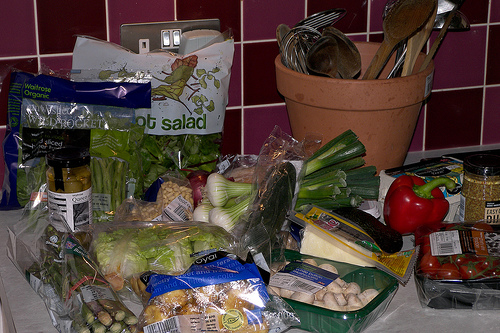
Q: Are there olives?
A: Yes, there are olives.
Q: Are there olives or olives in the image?
A: Yes, there are olives.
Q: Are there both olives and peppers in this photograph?
A: Yes, there are both olives and a pepper.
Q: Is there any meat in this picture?
A: No, there is no meat.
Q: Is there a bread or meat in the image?
A: No, there are no meat or breads.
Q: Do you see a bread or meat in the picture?
A: No, there are no meat or breads.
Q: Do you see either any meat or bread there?
A: No, there are no meat or breads.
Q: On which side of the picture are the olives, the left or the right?
A: The olives are on the left of the image.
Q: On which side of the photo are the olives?
A: The olives are on the left of the image.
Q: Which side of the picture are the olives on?
A: The olives are on the left of the image.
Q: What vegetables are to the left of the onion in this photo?
A: The vegetables are olives.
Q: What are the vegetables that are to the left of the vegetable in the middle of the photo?
A: The vegetables are olives.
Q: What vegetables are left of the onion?
A: The vegetables are olives.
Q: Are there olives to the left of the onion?
A: Yes, there are olives to the left of the onion.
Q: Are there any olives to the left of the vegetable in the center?
A: Yes, there are olives to the left of the onion.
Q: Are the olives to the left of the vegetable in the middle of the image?
A: Yes, the olives are to the left of the onion.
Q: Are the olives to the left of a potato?
A: No, the olives are to the left of the onion.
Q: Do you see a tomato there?
A: Yes, there is a tomato.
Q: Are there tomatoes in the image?
A: Yes, there is a tomato.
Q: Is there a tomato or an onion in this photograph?
A: Yes, there is a tomato.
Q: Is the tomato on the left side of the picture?
A: No, the tomato is on the right of the image.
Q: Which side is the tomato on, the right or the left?
A: The tomato is on the right of the image.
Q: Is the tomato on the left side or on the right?
A: The tomato is on the right of the image.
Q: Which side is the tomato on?
A: The tomato is on the right of the image.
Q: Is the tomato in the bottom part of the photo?
A: Yes, the tomato is in the bottom of the image.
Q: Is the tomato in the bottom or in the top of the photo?
A: The tomato is in the bottom of the image.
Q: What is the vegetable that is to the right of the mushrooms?
A: The vegetable is a tomato.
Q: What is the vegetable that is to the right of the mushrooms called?
A: The vegetable is a tomato.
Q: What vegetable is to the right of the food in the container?
A: The vegetable is a tomato.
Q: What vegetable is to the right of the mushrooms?
A: The vegetable is a tomato.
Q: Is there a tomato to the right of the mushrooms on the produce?
A: Yes, there is a tomato to the right of the mushrooms.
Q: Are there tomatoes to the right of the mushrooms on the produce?
A: Yes, there is a tomato to the right of the mushrooms.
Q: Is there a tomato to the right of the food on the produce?
A: Yes, there is a tomato to the right of the mushrooms.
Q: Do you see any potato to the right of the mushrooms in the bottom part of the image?
A: No, there is a tomato to the right of the mushrooms.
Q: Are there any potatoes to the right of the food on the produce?
A: No, there is a tomato to the right of the mushrooms.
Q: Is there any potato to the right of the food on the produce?
A: No, there is a tomato to the right of the mushrooms.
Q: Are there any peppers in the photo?
A: Yes, there is a pepper.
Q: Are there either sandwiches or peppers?
A: Yes, there is a pepper.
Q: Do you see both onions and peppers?
A: Yes, there are both a pepper and an onion.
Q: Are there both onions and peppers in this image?
A: Yes, there are both a pepper and an onion.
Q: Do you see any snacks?
A: No, there are no snacks.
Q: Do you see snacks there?
A: No, there are no snacks.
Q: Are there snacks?
A: No, there are no snacks.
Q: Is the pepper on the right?
A: Yes, the pepper is on the right of the image.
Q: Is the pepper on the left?
A: No, the pepper is on the right of the image.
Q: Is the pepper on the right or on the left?
A: The pepper is on the right of the image.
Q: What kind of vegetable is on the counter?
A: The vegetable is a pepper.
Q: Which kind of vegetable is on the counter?
A: The vegetable is a pepper.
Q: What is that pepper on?
A: The pepper is on the counter.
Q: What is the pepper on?
A: The pepper is on the counter.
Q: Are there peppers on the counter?
A: Yes, there is a pepper on the counter.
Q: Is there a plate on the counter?
A: No, there is a pepper on the counter.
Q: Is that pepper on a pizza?
A: No, the pepper is on a counter.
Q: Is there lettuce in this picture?
A: Yes, there is lettuce.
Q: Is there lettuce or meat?
A: Yes, there is lettuce.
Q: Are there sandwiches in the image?
A: No, there are no sandwiches.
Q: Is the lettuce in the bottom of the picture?
A: Yes, the lettuce is in the bottom of the image.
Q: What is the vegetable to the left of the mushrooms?
A: The vegetable is lettuce.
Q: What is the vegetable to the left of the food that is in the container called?
A: The vegetable is lettuce.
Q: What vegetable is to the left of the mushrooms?
A: The vegetable is lettuce.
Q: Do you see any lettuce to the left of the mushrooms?
A: Yes, there is lettuce to the left of the mushrooms.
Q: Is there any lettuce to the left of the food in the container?
A: Yes, there is lettuce to the left of the mushrooms.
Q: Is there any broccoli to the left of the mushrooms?
A: No, there is lettuce to the left of the mushrooms.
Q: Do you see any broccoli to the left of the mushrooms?
A: No, there is lettuce to the left of the mushrooms.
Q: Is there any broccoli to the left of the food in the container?
A: No, there is lettuce to the left of the mushrooms.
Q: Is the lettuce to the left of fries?
A: No, the lettuce is to the left of the mushrooms.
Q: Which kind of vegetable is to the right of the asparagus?
A: The vegetable is lettuce.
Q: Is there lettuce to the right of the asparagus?
A: Yes, there is lettuce to the right of the asparagus.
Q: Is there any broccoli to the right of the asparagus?
A: No, there is lettuce to the right of the asparagus.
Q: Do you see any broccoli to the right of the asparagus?
A: No, there is lettuce to the right of the asparagus.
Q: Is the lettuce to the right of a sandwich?
A: No, the lettuce is to the right of the asparagus.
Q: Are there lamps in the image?
A: No, there are no lamps.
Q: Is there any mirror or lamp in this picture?
A: No, there are no lamps or mirrors.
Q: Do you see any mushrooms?
A: Yes, there are mushrooms.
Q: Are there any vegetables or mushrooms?
A: Yes, there are mushrooms.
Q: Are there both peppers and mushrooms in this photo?
A: Yes, there are both mushrooms and a pepper.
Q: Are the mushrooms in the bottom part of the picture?
A: Yes, the mushrooms are in the bottom of the image.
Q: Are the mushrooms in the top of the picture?
A: No, the mushrooms are in the bottom of the image.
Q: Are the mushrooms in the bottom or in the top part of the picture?
A: The mushrooms are in the bottom of the image.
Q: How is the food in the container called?
A: The food is mushrooms.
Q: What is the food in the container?
A: The food is mushrooms.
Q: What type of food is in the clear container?
A: The food is mushrooms.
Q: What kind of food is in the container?
A: The food is mushrooms.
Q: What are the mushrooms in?
A: The mushrooms are in the container.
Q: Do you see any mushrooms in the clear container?
A: Yes, there are mushrooms in the container.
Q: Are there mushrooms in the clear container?
A: Yes, there are mushrooms in the container.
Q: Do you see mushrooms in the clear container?
A: Yes, there are mushrooms in the container.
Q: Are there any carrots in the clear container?
A: No, there are mushrooms in the container.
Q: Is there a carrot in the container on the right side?
A: No, there are mushrooms in the container.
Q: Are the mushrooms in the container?
A: Yes, the mushrooms are in the container.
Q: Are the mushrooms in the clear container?
A: Yes, the mushrooms are in the container.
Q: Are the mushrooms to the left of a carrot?
A: No, the mushrooms are to the left of a tomato.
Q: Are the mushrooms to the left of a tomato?
A: Yes, the mushrooms are to the left of a tomato.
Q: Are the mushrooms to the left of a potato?
A: No, the mushrooms are to the left of a tomato.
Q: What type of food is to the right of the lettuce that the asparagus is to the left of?
A: The food is mushrooms.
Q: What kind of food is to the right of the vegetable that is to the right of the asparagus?
A: The food is mushrooms.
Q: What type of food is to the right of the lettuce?
A: The food is mushrooms.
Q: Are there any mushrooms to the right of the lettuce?
A: Yes, there are mushrooms to the right of the lettuce.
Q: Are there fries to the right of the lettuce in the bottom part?
A: No, there are mushrooms to the right of the lettuce.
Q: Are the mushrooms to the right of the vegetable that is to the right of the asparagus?
A: Yes, the mushrooms are to the right of the lettuce.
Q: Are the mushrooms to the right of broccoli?
A: No, the mushrooms are to the right of the lettuce.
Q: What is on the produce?
A: The mushrooms are on the produce.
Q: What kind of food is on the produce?
A: The food is mushrooms.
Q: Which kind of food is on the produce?
A: The food is mushrooms.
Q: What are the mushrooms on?
A: The mushrooms are on the produce.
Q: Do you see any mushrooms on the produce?
A: Yes, there are mushrooms on the produce.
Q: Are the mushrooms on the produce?
A: Yes, the mushrooms are on the produce.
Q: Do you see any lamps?
A: No, there are no lamps.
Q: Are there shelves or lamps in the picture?
A: No, there are no lamps or shelves.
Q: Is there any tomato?
A: Yes, there is a tomato.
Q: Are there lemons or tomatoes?
A: Yes, there is a tomato.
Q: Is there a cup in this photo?
A: No, there are no cups.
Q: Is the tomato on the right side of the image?
A: Yes, the tomato is on the right of the image.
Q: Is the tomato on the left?
A: No, the tomato is on the right of the image.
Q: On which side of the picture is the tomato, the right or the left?
A: The tomato is on the right of the image.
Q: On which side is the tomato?
A: The tomato is on the right of the image.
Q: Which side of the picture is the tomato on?
A: The tomato is on the right of the image.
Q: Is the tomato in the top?
A: No, the tomato is in the bottom of the image.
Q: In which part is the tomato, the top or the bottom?
A: The tomato is in the bottom of the image.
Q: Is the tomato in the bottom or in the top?
A: The tomato is in the bottom of the image.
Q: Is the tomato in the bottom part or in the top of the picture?
A: The tomato is in the bottom of the image.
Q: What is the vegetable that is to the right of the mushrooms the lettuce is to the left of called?
A: The vegetable is a tomato.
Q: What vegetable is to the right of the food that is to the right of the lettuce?
A: The vegetable is a tomato.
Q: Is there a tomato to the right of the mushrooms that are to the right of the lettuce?
A: Yes, there is a tomato to the right of the mushrooms.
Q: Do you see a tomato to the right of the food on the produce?
A: Yes, there is a tomato to the right of the mushrooms.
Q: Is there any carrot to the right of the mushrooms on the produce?
A: No, there is a tomato to the right of the mushrooms.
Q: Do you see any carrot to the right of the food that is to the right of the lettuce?
A: No, there is a tomato to the right of the mushrooms.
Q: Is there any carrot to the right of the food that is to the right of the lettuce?
A: No, there is a tomato to the right of the mushrooms.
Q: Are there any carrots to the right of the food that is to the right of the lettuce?
A: No, there is a tomato to the right of the mushrooms.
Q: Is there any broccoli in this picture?
A: No, there is no broccoli.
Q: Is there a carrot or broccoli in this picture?
A: No, there are no broccoli or carrots.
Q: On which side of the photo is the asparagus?
A: The asparagus is on the left of the image.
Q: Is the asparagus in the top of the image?
A: No, the asparagus is in the bottom of the image.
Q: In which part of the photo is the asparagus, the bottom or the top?
A: The asparagus is in the bottom of the image.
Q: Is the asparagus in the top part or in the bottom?
A: The asparagus is in the bottom of the image.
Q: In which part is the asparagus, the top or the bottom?
A: The asparagus is in the bottom of the image.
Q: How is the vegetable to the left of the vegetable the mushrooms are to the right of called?
A: The vegetable is an asparagus.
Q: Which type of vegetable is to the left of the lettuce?
A: The vegetable is an asparagus.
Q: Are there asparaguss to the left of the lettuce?
A: Yes, there is an asparagus to the left of the lettuce.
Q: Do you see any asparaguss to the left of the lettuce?
A: Yes, there is an asparagus to the left of the lettuce.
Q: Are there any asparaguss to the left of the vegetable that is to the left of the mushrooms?
A: Yes, there is an asparagus to the left of the lettuce.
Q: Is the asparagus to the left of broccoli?
A: No, the asparagus is to the left of the lettuce.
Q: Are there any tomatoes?
A: Yes, there is a tomato.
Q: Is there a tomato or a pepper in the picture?
A: Yes, there is a tomato.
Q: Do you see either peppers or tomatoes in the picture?
A: Yes, there is a tomato.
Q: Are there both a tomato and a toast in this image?
A: No, there is a tomato but no toasts.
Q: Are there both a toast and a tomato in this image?
A: No, there is a tomato but no toasts.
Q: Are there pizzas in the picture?
A: No, there are no pizzas.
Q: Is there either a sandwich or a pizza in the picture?
A: No, there are no pizzas or sandwiches.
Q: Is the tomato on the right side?
A: Yes, the tomato is on the right of the image.